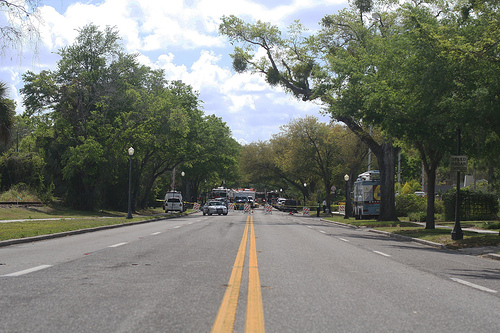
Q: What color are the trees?
A: Green.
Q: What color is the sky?
A: Blue.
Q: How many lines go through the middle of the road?
A: Two.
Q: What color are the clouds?
A: White.